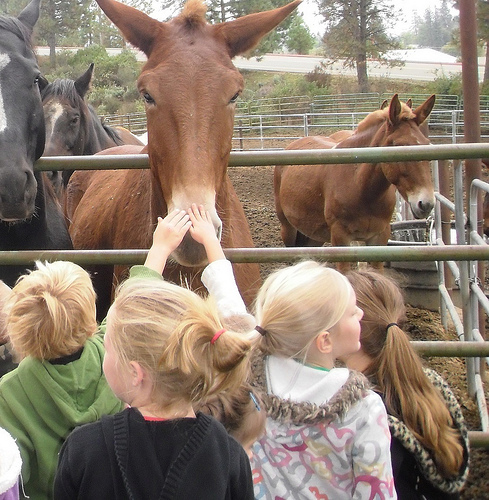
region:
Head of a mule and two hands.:
[82, 1, 308, 258]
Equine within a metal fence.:
[0, 0, 488, 227]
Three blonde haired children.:
[0, 253, 364, 494]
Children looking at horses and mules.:
[0, 0, 479, 496]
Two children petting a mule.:
[7, 0, 364, 494]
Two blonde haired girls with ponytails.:
[89, 250, 361, 414]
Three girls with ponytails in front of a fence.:
[95, 251, 469, 494]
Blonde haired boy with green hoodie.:
[1, 257, 101, 417]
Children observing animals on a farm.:
[0, 3, 487, 497]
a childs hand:
[181, 203, 221, 253]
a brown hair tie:
[256, 324, 264, 342]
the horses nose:
[415, 194, 436, 210]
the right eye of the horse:
[133, 89, 157, 116]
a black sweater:
[93, 447, 144, 481]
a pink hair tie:
[212, 329, 225, 342]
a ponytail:
[382, 340, 435, 411]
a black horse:
[44, 88, 82, 137]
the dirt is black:
[246, 184, 265, 209]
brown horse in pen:
[253, 83, 474, 302]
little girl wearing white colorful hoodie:
[234, 318, 406, 498]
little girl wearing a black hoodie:
[35, 393, 281, 498]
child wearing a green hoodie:
[0, 252, 170, 498]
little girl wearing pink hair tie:
[177, 303, 255, 381]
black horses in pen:
[0, 0, 200, 320]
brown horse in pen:
[49, 0, 300, 347]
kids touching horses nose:
[117, 178, 293, 341]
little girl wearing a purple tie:
[234, 289, 298, 367]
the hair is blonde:
[274, 276, 327, 336]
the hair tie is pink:
[208, 326, 225, 344]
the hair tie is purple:
[253, 323, 266, 336]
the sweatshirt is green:
[16, 375, 94, 415]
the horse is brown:
[314, 170, 394, 213]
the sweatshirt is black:
[86, 428, 211, 495]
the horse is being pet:
[118, 10, 261, 276]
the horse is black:
[39, 76, 82, 162]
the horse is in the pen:
[253, 99, 430, 264]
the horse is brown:
[137, 19, 230, 213]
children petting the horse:
[122, 167, 242, 343]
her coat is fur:
[387, 370, 482, 474]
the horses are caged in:
[6, 117, 472, 410]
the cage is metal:
[2, 112, 483, 273]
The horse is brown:
[258, 99, 430, 240]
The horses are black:
[4, 60, 115, 238]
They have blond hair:
[127, 274, 335, 365]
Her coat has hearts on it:
[259, 401, 379, 492]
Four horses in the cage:
[11, 27, 452, 309]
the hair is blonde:
[120, 272, 258, 407]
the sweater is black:
[105, 416, 210, 490]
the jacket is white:
[298, 385, 385, 490]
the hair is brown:
[393, 358, 474, 461]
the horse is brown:
[388, 134, 451, 236]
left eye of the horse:
[137, 77, 170, 114]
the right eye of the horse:
[226, 77, 248, 113]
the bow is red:
[194, 329, 235, 354]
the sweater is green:
[15, 357, 90, 433]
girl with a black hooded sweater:
[40, 283, 266, 498]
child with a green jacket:
[4, 197, 191, 498]